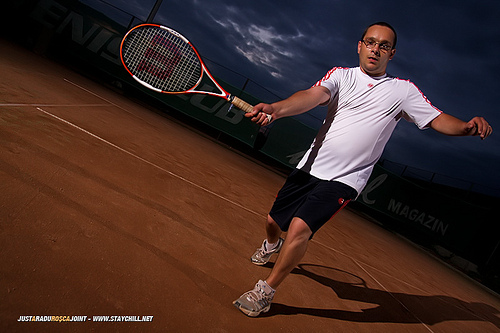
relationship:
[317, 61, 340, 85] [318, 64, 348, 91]
stripe on sleeve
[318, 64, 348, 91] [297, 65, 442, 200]
sleeve of shirt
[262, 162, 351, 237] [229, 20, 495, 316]
shorts on man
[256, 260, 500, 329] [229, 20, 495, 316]
shadow of a man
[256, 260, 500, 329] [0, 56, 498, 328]
shadow on ground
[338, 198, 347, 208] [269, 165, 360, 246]
parts on shorts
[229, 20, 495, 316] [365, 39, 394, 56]
man wearing glasses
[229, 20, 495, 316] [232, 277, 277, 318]
man wearing shoe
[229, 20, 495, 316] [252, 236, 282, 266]
man wearing shoe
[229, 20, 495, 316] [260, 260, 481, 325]
man casting shadow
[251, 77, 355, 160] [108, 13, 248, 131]
arm with racket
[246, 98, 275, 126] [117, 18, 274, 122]
hand holding tennis racket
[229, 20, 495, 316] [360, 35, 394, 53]
man wearing glasses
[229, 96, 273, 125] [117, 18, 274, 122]
handle on tennis racket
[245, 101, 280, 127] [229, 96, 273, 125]
hand on handle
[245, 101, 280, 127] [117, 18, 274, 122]
hand holding tennis racket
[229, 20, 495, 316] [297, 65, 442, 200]
man wearing shirt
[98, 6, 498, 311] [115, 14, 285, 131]
man holding tennis racket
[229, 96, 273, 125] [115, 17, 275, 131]
handle on racket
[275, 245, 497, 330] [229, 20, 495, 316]
shadow of man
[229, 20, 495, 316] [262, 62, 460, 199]
man wearing white shirt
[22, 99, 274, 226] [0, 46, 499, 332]
lines on tennis court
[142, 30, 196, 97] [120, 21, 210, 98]
red w on strings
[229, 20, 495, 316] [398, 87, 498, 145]
man has raised arm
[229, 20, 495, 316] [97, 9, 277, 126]
man holding racket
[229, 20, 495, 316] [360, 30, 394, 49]
man wearing glasses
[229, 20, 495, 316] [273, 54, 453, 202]
man wearing shirt